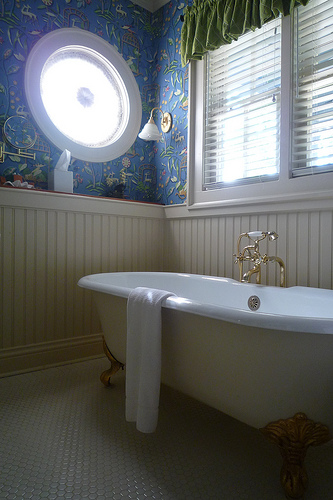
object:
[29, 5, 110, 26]
wallpaper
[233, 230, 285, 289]
fixtures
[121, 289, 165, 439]
towel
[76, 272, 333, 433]
tub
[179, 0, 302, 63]
curtain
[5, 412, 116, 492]
floor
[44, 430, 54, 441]
tiles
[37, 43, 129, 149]
window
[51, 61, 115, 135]
sunlight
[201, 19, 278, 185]
blinds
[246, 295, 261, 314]
drain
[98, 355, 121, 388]
claw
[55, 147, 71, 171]
tissue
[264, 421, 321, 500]
claws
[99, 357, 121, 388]
stand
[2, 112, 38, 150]
mirror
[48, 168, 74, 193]
box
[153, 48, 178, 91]
wall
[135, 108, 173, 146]
light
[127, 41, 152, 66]
design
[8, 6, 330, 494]
bathroom